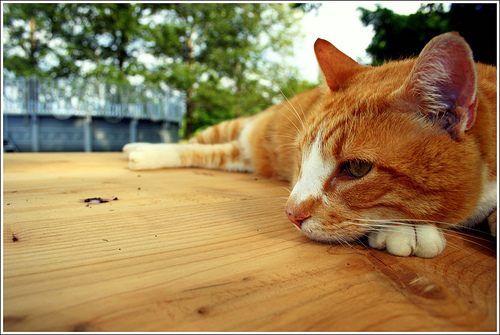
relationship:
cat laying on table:
[122, 28, 495, 266] [14, 149, 498, 333]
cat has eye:
[122, 28, 495, 266] [336, 155, 380, 178]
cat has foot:
[122, 28, 495, 266] [367, 220, 447, 259]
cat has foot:
[122, 28, 495, 266] [124, 141, 195, 172]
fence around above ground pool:
[4, 78, 189, 122] [4, 77, 183, 153]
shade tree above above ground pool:
[7, 6, 131, 92] [4, 77, 183, 153]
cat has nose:
[122, 28, 495, 266] [286, 210, 311, 227]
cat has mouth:
[122, 28, 495, 266] [316, 220, 378, 245]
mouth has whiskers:
[316, 220, 378, 245] [332, 214, 498, 291]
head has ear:
[287, 60, 487, 241] [315, 34, 361, 88]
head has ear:
[287, 60, 487, 241] [393, 30, 477, 136]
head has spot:
[287, 60, 487, 241] [294, 135, 338, 199]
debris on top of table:
[83, 195, 112, 205] [14, 149, 498, 333]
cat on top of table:
[122, 28, 495, 266] [14, 149, 498, 333]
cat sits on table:
[122, 28, 495, 266] [14, 149, 498, 333]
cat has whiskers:
[122, 28, 495, 266] [332, 214, 498, 291]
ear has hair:
[393, 30, 477, 136] [410, 38, 450, 122]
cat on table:
[122, 28, 495, 266] [14, 149, 498, 333]